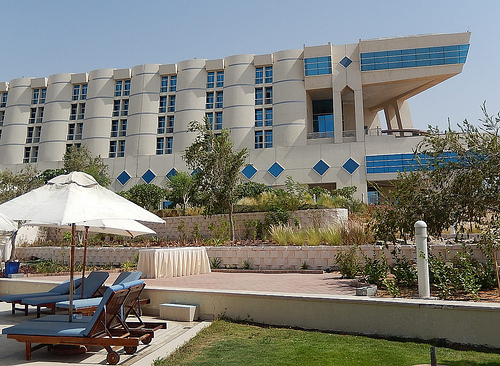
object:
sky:
[0, 2, 363, 44]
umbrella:
[0, 169, 170, 244]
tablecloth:
[134, 246, 213, 278]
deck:
[363, 91, 479, 139]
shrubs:
[329, 245, 493, 300]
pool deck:
[2, 280, 182, 364]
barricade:
[412, 216, 434, 297]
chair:
[0, 269, 109, 321]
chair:
[0, 280, 171, 363]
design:
[310, 158, 331, 178]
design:
[341, 157, 361, 175]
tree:
[179, 111, 253, 244]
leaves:
[178, 112, 251, 220]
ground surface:
[152, 316, 500, 364]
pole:
[410, 216, 433, 298]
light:
[413, 227, 428, 236]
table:
[134, 242, 216, 280]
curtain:
[134, 244, 213, 279]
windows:
[254, 113, 264, 121]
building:
[0, 27, 499, 240]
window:
[37, 97, 45, 105]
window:
[78, 93, 87, 101]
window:
[123, 83, 133, 91]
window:
[166, 85, 180, 92]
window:
[207, 75, 215, 84]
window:
[261, 75, 274, 85]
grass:
[266, 218, 371, 246]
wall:
[213, 243, 326, 271]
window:
[253, 85, 265, 94]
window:
[255, 71, 265, 80]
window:
[254, 136, 263, 144]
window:
[254, 64, 266, 73]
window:
[165, 105, 176, 113]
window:
[254, 108, 265, 115]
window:
[263, 141, 275, 150]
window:
[253, 119, 265, 129]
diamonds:
[237, 161, 259, 183]